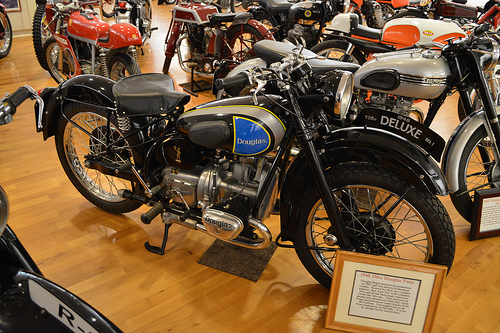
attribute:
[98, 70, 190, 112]
seat — gray, big, black, grey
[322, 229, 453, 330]
frame — wooden, wood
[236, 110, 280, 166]
logo — blue, yellow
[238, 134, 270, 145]
douglas — yellow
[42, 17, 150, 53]
motorcycle — orange, shiny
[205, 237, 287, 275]
rug — small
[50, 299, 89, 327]
r — black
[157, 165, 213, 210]
tank — silver, black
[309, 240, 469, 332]
photo — framed, wooden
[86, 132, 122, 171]
spokes — silver, metal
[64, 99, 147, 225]
wheel — black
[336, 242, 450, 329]
picture — framed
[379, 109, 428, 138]
deluxe — gray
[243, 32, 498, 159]
motorcycle — black, silver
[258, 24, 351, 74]
seat — long, flat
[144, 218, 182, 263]
kickstand — black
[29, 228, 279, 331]
floor — wooden, wood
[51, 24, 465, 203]
motorcycles — big, displayed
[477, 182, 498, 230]
certificate — framed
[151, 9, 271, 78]
motorcycle — red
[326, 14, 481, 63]
motorcycle — orange, white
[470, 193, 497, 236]
frame — black, red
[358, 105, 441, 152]
sign — curved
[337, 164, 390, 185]
treads — triangular